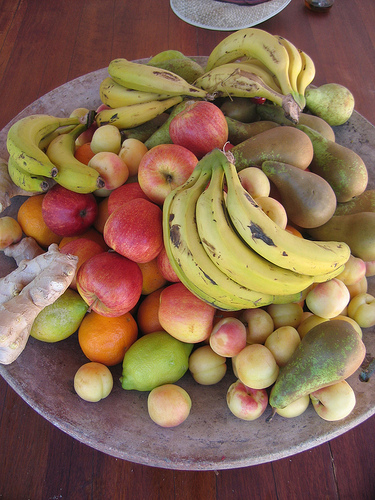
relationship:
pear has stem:
[265, 319, 367, 425] [266, 406, 276, 421]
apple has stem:
[102, 197, 164, 264] [107, 247, 115, 252]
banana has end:
[46, 122, 106, 193] [96, 176, 106, 188]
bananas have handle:
[161, 149, 348, 311] [190, 148, 235, 173]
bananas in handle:
[161, 149, 348, 311] [190, 148, 235, 173]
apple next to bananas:
[102, 197, 164, 264] [161, 149, 348, 311]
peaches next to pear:
[207, 314, 280, 389] [265, 319, 367, 425]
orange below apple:
[77, 307, 141, 366] [78, 249, 143, 315]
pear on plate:
[265, 319, 367, 425] [0, 54, 374, 473]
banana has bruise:
[222, 159, 351, 275] [248, 223, 278, 248]